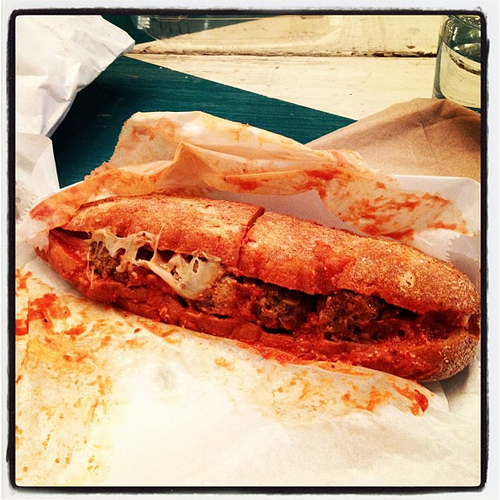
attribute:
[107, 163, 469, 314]
bread — crusty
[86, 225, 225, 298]
cheese — melted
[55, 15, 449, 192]
table — white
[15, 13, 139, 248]
paper — white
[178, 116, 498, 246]
paper — crumpled, white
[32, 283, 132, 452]
stains — orange